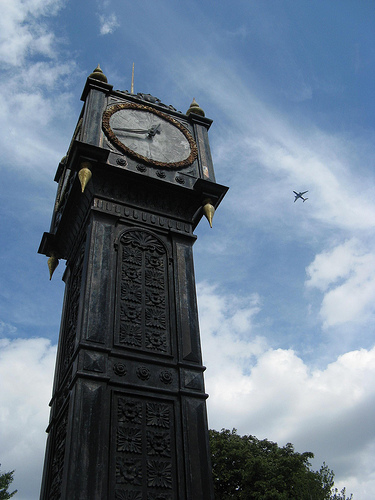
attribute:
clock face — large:
[104, 94, 198, 171]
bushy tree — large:
[206, 430, 359, 495]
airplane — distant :
[288, 188, 313, 207]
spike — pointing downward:
[73, 160, 93, 196]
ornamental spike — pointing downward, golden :
[202, 202, 219, 228]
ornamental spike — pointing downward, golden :
[44, 253, 61, 278]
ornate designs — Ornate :
[96, 223, 195, 498]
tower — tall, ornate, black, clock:
[37, 57, 230, 494]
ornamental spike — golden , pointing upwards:
[82, 64, 107, 75]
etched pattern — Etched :
[106, 383, 189, 497]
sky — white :
[233, 227, 372, 409]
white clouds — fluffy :
[264, 233, 372, 375]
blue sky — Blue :
[281, 15, 371, 94]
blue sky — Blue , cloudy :
[2, 2, 373, 499]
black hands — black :
[112, 118, 165, 141]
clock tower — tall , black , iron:
[27, 63, 230, 493]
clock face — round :
[100, 96, 200, 168]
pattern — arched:
[106, 223, 176, 360]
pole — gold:
[126, 58, 139, 93]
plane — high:
[290, 186, 313, 206]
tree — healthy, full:
[208, 426, 356, 498]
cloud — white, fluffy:
[196, 286, 362, 495]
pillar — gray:
[36, 208, 221, 498]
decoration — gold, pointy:
[201, 201, 218, 230]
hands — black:
[111, 124, 167, 141]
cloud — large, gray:
[2, 332, 61, 499]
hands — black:
[109, 119, 164, 144]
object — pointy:
[201, 201, 219, 229]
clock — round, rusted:
[99, 99, 199, 174]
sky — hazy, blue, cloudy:
[2, 2, 362, 499]